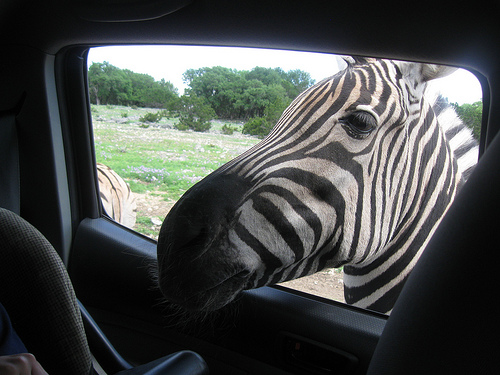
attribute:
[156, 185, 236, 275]
nose — black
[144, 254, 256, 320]
mouth — hairy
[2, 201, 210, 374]
carseat — black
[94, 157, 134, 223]
rear end — Hilarious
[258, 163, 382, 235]
stripes — black, white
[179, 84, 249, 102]
trees — forest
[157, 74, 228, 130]
bushes — forest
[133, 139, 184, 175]
grass — green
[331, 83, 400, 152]
lashes — long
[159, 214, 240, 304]
muzzle — black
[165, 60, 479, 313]
zebra — black, white, looking in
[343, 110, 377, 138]
eye — black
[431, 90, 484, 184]
mane — white, dark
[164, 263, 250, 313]
mouth — closed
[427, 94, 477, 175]
mane — black, white, striped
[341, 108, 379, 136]
eye — black rimmed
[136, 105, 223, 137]
bushes — short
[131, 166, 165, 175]
patch — small, gray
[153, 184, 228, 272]
nose — black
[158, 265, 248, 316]
mouth — closed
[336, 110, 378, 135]
eye — black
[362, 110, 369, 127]
eyelash — long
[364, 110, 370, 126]
eyelash — long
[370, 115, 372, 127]
eyelash — long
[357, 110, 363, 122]
eyelash — long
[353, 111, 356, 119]
eyelash — long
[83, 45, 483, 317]
window — open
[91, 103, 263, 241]
grass — short, sparse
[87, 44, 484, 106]
sky — overcast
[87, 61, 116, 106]
tree — green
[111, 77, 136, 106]
tree — green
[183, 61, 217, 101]
tree — green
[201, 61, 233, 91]
tree — green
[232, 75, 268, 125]
tree — green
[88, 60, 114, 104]
tree — leafy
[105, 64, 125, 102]
tree — leafy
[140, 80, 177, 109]
tree — leafy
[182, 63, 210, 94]
tree — leafy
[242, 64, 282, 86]
tree — leafy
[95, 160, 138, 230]
zebra — walking away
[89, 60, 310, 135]
trees — green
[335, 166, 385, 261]
cheek — flat